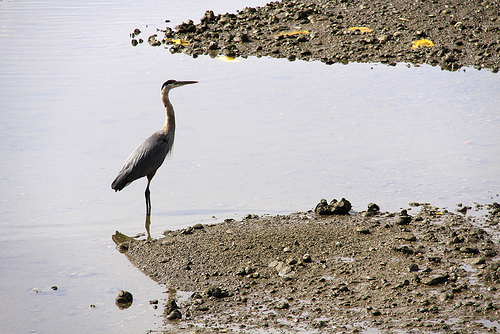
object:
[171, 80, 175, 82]
eye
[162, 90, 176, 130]
neck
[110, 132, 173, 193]
wing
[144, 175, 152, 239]
legs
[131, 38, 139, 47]
rocks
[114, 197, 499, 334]
dirt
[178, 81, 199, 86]
beak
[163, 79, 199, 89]
head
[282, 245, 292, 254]
stone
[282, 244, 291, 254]
stone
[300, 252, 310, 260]
stone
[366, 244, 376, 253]
stone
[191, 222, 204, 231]
stone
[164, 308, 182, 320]
rock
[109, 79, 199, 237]
bird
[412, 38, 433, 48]
spots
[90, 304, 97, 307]
rock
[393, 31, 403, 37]
rock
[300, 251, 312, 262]
rock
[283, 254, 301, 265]
rock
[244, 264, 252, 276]
rock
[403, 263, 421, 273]
rock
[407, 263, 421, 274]
rock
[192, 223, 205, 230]
rock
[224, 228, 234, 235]
rock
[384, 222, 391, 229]
rock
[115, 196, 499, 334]
ground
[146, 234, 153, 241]
feet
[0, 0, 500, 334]
ripples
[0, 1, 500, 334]
water